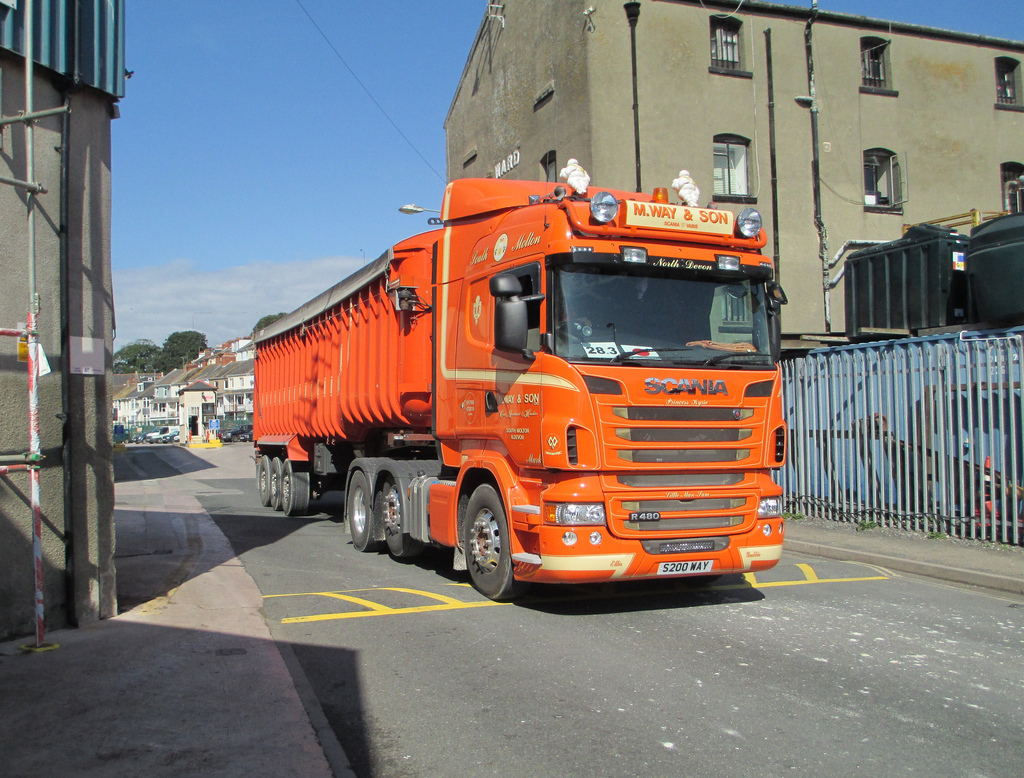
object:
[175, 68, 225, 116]
sky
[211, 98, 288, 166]
sky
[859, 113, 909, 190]
window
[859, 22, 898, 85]
window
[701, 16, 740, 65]
window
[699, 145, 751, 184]
window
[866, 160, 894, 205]
window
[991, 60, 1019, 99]
window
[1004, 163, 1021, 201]
window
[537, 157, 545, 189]
window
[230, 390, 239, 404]
window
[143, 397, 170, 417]
window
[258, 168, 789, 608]
dump truck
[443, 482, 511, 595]
wheel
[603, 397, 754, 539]
grill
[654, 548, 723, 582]
license plate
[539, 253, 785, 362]
windshield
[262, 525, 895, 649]
lines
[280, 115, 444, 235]
sky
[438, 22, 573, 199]
building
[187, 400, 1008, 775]
street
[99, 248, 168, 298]
clouds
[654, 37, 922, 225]
building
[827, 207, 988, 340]
building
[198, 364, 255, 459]
building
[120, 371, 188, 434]
building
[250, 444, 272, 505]
wheel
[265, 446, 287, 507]
wheel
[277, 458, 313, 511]
wheel